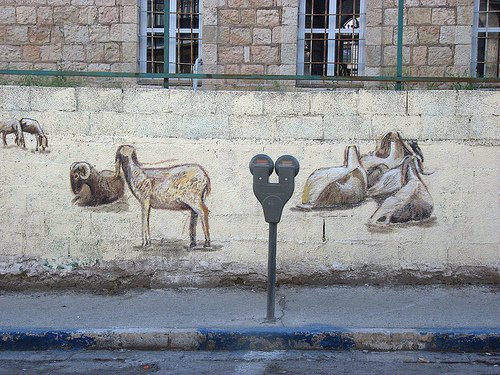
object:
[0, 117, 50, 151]
drawings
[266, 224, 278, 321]
pole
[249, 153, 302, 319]
parkingmeter.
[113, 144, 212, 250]
animal drawing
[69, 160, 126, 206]
animal drawing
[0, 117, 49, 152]
animal drawing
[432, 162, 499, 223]
ground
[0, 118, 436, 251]
rams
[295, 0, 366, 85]
window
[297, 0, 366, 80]
bars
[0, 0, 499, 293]
wall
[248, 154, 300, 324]
parking meter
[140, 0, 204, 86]
window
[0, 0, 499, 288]
building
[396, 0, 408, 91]
pole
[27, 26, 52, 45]
brick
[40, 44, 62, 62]
brick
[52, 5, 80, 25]
brick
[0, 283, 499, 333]
gray sidewalk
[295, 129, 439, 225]
goats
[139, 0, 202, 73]
metal bar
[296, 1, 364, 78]
metal bar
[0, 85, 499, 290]
mural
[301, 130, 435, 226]
drawing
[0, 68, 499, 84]
pole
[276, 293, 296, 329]
crack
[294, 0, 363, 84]
metal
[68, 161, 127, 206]
drawings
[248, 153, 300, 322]
meter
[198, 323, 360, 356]
painting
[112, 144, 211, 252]
drawing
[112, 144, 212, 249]
goat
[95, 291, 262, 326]
cracks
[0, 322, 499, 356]
paint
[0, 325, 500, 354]
curb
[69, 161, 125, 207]
buffalo